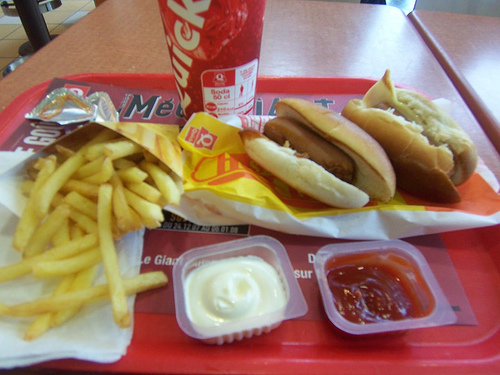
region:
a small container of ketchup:
[310, 238, 459, 332]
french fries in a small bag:
[3, 115, 186, 333]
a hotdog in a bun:
[238, 93, 394, 210]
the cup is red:
[154, 0, 267, 129]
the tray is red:
[5, 70, 498, 370]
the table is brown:
[1, 1, 499, 248]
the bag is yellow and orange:
[180, 110, 499, 235]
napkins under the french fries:
[1, 146, 151, 369]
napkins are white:
[0, 142, 150, 374]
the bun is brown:
[237, 92, 395, 204]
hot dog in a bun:
[253, 95, 388, 199]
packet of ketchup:
[323, 241, 445, 329]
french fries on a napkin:
[18, 286, 124, 337]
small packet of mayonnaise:
[177, 239, 295, 329]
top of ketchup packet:
[32, 83, 97, 129]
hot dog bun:
[345, 72, 477, 183]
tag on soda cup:
[197, 64, 267, 111]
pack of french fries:
[29, 149, 160, 223]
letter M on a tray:
[121, 86, 161, 123]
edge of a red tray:
[248, 351, 388, 373]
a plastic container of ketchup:
[316, 239, 452, 330]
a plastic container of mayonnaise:
[178, 237, 293, 337]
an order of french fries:
[0, 132, 177, 337]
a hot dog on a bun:
[258, 111, 363, 180]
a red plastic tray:
[0, 74, 499, 370]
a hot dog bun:
[237, 97, 394, 211]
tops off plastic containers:
[24, 87, 121, 127]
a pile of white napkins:
[2, 152, 134, 365]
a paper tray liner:
[0, 79, 468, 327]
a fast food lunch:
[6, 42, 498, 369]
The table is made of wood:
[282, 5, 449, 72]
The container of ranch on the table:
[164, 229, 309, 346]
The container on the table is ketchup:
[313, 233, 461, 341]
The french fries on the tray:
[10, 129, 157, 326]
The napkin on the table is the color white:
[8, 316, 157, 371]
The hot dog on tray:
[236, 96, 404, 213]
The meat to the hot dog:
[263, 114, 359, 182]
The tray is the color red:
[131, 218, 497, 373]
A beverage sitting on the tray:
[153, 0, 271, 135]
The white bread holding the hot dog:
[275, 89, 434, 186]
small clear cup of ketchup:
[312, 245, 422, 357]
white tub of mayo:
[171, 249, 298, 346]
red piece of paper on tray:
[424, 252, 476, 265]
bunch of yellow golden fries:
[26, 162, 138, 326]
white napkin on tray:
[37, 262, 132, 349]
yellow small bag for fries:
[76, 87, 192, 207]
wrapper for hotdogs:
[179, 123, 495, 258]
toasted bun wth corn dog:
[249, 104, 362, 221]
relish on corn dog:
[381, 86, 441, 153]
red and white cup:
[156, 33, 264, 127]